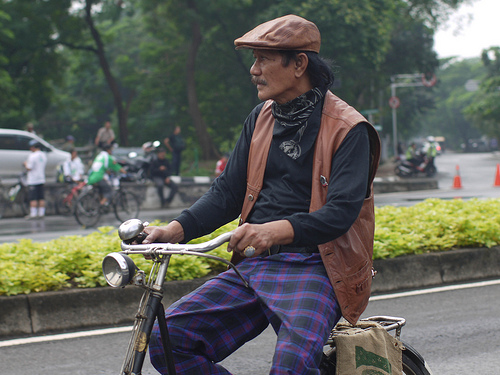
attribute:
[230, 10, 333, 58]
hat — brown, leather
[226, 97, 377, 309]
vest — leather, brown, pinned, brown leather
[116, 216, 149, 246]
bell — silver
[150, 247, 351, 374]
pants — plaid, purple, multicolored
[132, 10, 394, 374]
man — looking away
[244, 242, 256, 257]
ring — worn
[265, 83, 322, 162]
scarf — black, gray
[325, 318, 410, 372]
bag — burlap, brown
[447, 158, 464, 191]
cone — orange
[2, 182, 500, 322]
plants — green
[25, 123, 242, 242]
people — gathered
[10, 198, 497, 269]
bush — green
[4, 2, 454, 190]
trees — tall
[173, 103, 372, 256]
shirt — black